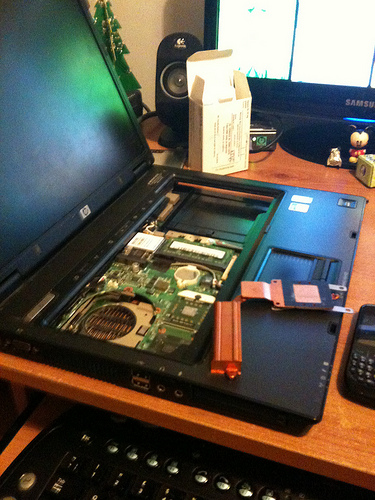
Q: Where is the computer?
A: On the desk.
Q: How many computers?
A: One.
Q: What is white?
A: The box.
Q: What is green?
A: Motherboard.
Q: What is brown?
A: Desk.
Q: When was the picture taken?
A: Daytime.